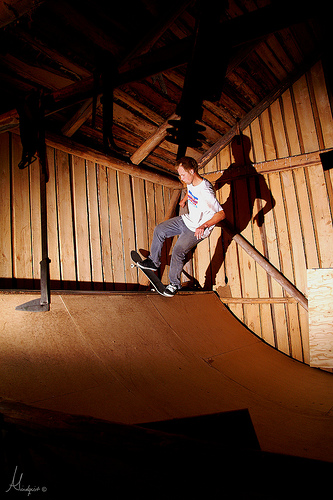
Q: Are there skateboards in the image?
A: Yes, there is a skateboard.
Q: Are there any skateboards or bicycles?
A: Yes, there is a skateboard.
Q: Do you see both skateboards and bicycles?
A: No, there is a skateboard but no bicycles.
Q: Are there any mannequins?
A: No, there are no mannequins.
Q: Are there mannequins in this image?
A: No, there are no mannequins.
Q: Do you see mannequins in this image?
A: No, there are no mannequins.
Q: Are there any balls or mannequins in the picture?
A: No, there are no mannequins or balls.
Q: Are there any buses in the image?
A: No, there are no buses.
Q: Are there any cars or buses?
A: No, there are no buses or cars.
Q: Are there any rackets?
A: No, there are no rackets.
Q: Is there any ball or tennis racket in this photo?
A: No, there are no rackets or balls.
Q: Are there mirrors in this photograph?
A: No, there are no mirrors.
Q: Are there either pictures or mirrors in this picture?
A: No, there are no mirrors or pictures.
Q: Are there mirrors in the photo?
A: No, there are no mirrors.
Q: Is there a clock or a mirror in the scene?
A: No, there are no mirrors or clocks.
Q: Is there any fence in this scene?
A: No, there are no fences.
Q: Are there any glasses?
A: No, there are no glasses.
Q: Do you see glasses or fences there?
A: No, there are no glasses or fences.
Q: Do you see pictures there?
A: No, there are no pictures.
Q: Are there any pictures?
A: No, there are no pictures.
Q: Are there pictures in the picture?
A: No, there are no pictures.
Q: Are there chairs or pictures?
A: No, there are no pictures or chairs.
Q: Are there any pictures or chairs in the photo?
A: No, there are no pictures or chairs.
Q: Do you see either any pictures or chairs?
A: No, there are no pictures or chairs.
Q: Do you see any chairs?
A: No, there are no chairs.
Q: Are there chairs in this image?
A: No, there are no chairs.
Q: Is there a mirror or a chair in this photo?
A: No, there are no chairs or mirrors.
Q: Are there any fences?
A: No, there are no fences.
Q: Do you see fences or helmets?
A: No, there are no fences or helmets.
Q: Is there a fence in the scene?
A: No, there are no fences.